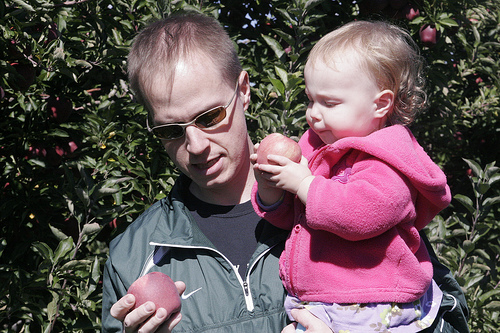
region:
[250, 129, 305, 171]
a red apple in a baby's hands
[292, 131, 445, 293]
a fuzzy pink coat on a baby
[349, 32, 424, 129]
curly blonde hair on a baby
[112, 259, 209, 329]
a red apple in a man's hand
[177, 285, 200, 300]
a white Nike swoosh symbol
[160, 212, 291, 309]
a white zipper on the man's jacket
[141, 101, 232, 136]
sunglasses on the man's face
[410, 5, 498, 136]
apple trees in the background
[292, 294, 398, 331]
a purple flowered shirt on the baby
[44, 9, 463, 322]
a man looking at apples with a baby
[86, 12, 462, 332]
a man and a toddler holding apples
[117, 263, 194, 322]
an apple that has been picked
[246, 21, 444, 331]
the little girl is holding an apple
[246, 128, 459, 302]
a warm pink fuzzy jacket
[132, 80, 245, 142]
sunglasses that the man is wearing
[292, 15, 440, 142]
the little girl has curly hair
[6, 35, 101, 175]
apples hanging on the plants in the background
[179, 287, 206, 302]
nike logo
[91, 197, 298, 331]
a dark green nike pull over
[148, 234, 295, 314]
the zipper on the pullover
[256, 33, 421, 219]
baby holding an apple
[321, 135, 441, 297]
pink fuzzy small jacket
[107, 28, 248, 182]
man wearing brown sunglasses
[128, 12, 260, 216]
man with short blond hair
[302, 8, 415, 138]
baby with blond hair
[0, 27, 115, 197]
leaves on a tree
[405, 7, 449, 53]
apples in a tree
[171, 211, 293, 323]
white zipper of a jacket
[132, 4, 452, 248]
a man and a baby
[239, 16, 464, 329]
baby wearing a pink jacket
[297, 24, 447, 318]
baby wearing pink jacket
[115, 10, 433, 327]
man holding baby girl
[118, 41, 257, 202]
man wearing dark glasses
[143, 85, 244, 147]
wire glasses with dark lenses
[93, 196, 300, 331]
grey Nike wind breaker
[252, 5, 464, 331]
baby holding red apple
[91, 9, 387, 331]
father holding red apple and baby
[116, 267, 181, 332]
large red apple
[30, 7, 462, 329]
apple trees located behind father and daughter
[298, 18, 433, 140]
blonde curls on baby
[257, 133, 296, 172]
APPLE IS IN THE BABY'S HAND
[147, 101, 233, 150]
GLASSES ARE ON THE GENTLEMAN'S FACE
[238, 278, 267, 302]
ZIPPER IS LOCATED ON THE JACKET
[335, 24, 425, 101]
BABY HAS BLONDE HAIR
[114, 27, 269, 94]
MAN HAS THINNING HAIR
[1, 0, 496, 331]
APPLE TREES ARE IN THE BACKGROUND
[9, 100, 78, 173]
APPLES ARE IN THE TREES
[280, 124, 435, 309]
BABY IS WEARING PINK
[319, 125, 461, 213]
BABY'S JACKET HAS A HOOD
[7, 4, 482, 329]
MAN IS HOLDING BABY